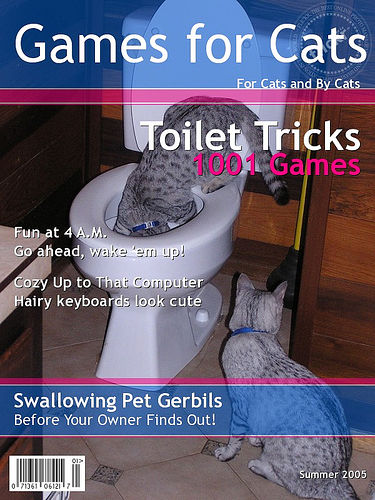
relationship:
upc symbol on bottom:
[12, 455, 93, 494] [6, 490, 374, 497]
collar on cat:
[229, 323, 272, 341] [206, 269, 374, 496]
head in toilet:
[132, 223, 167, 239] [69, 19, 296, 398]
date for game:
[297, 467, 368, 484] [14, 21, 146, 73]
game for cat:
[14, 21, 146, 73] [206, 269, 374, 496]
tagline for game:
[12, 387, 234, 434] [14, 21, 146, 73]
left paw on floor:
[210, 445, 239, 463] [44, 260, 369, 499]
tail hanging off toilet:
[239, 108, 296, 205] [69, 19, 296, 398]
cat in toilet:
[91, 98, 291, 233] [69, 19, 296, 398]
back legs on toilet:
[197, 133, 246, 204] [69, 19, 296, 398]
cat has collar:
[206, 269, 374, 496] [229, 323, 272, 341]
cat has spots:
[206, 269, 374, 496] [260, 352, 304, 379]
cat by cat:
[206, 269, 374, 496] [91, 98, 291, 233]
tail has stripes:
[239, 108, 296, 205] [257, 147, 285, 196]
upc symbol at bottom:
[12, 455, 93, 494] [6, 490, 374, 497]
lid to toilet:
[130, 3, 277, 161] [69, 19, 296, 398]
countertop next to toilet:
[0, 224, 52, 319] [69, 19, 296, 398]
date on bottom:
[297, 467, 368, 484] [6, 490, 374, 497]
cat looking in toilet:
[91, 98, 291, 233] [69, 19, 296, 398]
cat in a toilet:
[91, 98, 291, 233] [69, 19, 296, 398]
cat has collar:
[91, 98, 291, 233] [131, 222, 163, 230]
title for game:
[5, 7, 373, 82] [14, 21, 146, 73]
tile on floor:
[65, 408, 223, 492] [44, 260, 369, 499]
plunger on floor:
[269, 76, 311, 317] [44, 260, 369, 499]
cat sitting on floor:
[206, 269, 374, 496] [44, 260, 369, 499]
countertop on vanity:
[0, 224, 52, 319] [2, 316, 60, 500]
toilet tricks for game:
[142, 119, 369, 159] [14, 21, 146, 73]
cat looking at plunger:
[206, 269, 374, 496] [269, 76, 311, 317]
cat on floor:
[206, 269, 374, 496] [44, 260, 369, 499]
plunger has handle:
[269, 76, 311, 317] [295, 99, 309, 248]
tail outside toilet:
[239, 108, 296, 205] [69, 19, 296, 398]